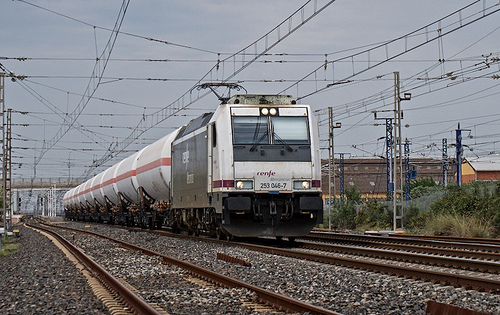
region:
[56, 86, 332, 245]
a white train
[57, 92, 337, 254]
a train going down the tracks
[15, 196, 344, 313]
brown train tracks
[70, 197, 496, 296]
a couple of train tracks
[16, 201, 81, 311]
gravel near the tracks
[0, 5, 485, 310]
a scene outside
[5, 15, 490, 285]
a scene during the day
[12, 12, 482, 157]
power lines over train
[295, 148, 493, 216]
a building in background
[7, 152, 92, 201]
a bridge in the background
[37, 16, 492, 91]
electrical wires of a trainyard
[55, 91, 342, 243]
red and white train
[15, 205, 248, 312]
set of train tracks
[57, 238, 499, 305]
three sets of train tracks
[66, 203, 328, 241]
wheels under a train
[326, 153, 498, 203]
red brick building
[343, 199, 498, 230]
green leafy bushes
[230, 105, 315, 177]
front window of a train engine car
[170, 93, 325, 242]
train engine car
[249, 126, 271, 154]
black windshield wiper for train window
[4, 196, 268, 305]
metal train tracks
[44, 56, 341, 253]
a train on the tracks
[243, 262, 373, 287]
rocks between the tracks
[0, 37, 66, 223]
poles between cables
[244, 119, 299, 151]
windshield wipers on the train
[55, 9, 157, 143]
wires in the sky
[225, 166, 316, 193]
white headlights on the train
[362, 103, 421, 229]
blue pole in the ground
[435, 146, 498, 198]
an orange building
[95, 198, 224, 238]
wheels on the train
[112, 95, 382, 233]
a train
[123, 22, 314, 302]
a train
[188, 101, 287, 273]
a train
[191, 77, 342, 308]
a train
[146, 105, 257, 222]
a train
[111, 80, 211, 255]
a train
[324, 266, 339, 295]
the stones are black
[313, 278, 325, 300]
the stones are black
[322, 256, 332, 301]
the stones are black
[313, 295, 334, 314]
the stones are black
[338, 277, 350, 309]
the stones are black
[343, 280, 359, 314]
the stones are black